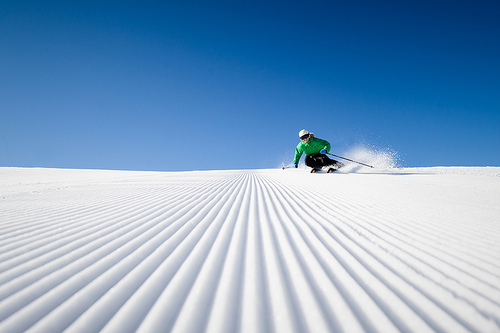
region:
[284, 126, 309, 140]
white helmet on skier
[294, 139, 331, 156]
green jacket on skier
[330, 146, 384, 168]
black ski pole in air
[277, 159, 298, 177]
black ski pole in hand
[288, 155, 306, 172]
green glove in hand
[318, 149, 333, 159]
green glove in hand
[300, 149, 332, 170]
black ski pants on person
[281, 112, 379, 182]
person skiing down hill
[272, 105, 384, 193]
person skiing down mountain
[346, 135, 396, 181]
snow spray caused by skiier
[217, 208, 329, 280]
lines in the snow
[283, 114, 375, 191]
skier with green jacket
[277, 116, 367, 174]
skier with white hat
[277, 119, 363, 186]
skier with black poles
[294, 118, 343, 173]
skier with sunglasses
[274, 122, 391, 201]
skies leaving wake in snow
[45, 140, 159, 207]
endless snow on the horizon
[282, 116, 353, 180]
skier with black pants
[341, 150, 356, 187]
There is a silver ski pole here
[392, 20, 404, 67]
There is a dark blue sky here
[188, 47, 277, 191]
Jackson Mingus took this photo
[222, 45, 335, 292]
This phone was taken in the season of winter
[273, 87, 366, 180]
a person is skiing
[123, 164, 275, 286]
the floor is covrerd of snow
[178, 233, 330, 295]
floor has lines of the skiing stick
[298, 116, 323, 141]
the helmet is gray in color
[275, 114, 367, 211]
the man is doing a trick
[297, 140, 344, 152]
the jacket is gray in color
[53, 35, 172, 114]
the sky is clear blue in color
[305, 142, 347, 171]
pants are black in color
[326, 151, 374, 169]
black ski pole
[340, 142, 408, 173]
snow from skier's skis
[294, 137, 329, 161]
green coat on skier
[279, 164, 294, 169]
black ski pole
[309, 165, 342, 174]
black skis in snow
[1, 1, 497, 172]
blue sky above horizon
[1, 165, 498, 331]
rippled snow on a slope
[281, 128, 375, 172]
a skier going down a slope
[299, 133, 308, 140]
black ski goggles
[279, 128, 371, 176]
a skier wearing a green coat